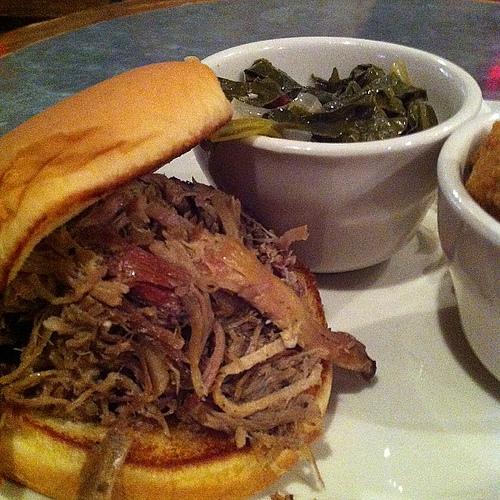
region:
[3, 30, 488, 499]
lunch on a plate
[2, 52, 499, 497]
dinner on a plate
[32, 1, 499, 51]
a blue table with a wooden edge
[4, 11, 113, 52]
a wooden edge on a table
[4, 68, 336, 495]
meat on a bun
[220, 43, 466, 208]
a cup of greens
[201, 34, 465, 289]
a white cup with food in it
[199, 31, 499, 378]
two white cups on a plate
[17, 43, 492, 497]
food on a white plate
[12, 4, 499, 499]
a plate of food on a table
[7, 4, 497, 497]
meal on a plate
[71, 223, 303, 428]
shredded pork on a plate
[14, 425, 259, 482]
toasted bun of a sandwich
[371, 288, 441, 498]
white plate where food is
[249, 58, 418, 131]
spinach in a bowl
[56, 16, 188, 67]
blue table where food is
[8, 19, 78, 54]
wooden edge of a blue table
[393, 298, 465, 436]
shadow casted on the plate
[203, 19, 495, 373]
bowls of food on plate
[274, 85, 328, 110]
onion in the spinach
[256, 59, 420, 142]
kales are in the bowl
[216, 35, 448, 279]
the bowl is white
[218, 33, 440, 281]
the bowl is shiny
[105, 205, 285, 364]
meat is between the burger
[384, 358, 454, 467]
the surface is white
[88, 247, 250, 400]
the meat is cooked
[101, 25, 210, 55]
the surface is grey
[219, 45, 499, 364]
the bowls are two in total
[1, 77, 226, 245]
the bread is brown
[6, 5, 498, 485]
the scene is indoors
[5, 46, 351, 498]
sandwich on the plate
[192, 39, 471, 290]
spinach in the bowl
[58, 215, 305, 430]
pulled pork in the sandwich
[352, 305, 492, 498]
the plate is white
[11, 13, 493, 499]
the food on the table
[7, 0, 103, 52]
the edge of the table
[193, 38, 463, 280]
the bowl on the plate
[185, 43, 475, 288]
the bowl is white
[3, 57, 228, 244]
the bun is toasted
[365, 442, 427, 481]
reflection on the plate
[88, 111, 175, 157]
A ROLL OF BREAD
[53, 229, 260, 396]
A PLATE OF FOOD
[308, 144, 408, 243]
A GLASS BOWL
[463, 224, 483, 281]
A GLASS BOWL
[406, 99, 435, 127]
A PIECE OF GREEN VEGATABLE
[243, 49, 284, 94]
A PIECE OF GREEN VEGATABLE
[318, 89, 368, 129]
A PIECE OF GREEN VEGATABLE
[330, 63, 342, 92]
A PIECE OF GREEN VEGATABLE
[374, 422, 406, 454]
PART OF THE TABLE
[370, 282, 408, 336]
PART OF THE TABLE